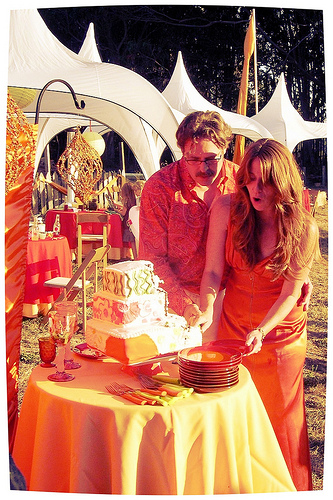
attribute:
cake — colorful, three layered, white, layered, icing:
[89, 261, 178, 362]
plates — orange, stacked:
[176, 347, 223, 391]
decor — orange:
[0, 134, 67, 181]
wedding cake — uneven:
[116, 260, 174, 328]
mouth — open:
[254, 197, 266, 203]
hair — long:
[277, 168, 311, 215]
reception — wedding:
[5, 43, 230, 323]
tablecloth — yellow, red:
[203, 391, 229, 401]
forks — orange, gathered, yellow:
[102, 385, 142, 405]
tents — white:
[40, 32, 177, 116]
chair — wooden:
[68, 218, 112, 260]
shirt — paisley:
[140, 182, 201, 244]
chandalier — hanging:
[60, 131, 102, 196]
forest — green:
[193, 34, 220, 66]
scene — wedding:
[51, 1, 285, 287]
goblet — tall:
[45, 290, 79, 354]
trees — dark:
[99, 10, 137, 46]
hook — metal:
[29, 73, 78, 102]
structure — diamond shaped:
[49, 114, 106, 204]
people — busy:
[119, 114, 307, 311]